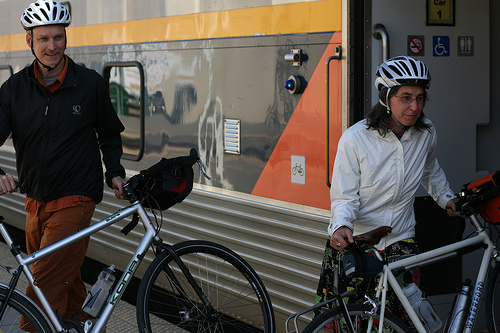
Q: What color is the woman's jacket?
A: White.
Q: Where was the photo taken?
A: Cleveland.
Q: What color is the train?
A: Silver.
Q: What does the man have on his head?
A: A helmet.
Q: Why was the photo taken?
A: For a magazine.